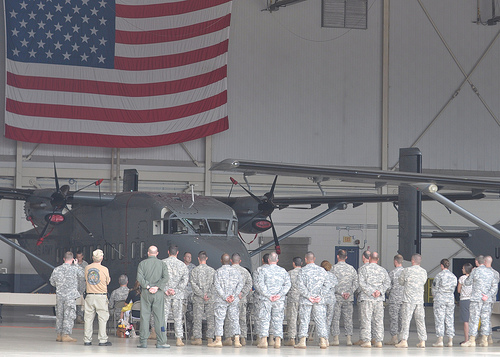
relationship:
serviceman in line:
[354, 247, 392, 343] [49, 244, 497, 345]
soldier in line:
[395, 254, 428, 348] [162, 248, 490, 354]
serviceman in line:
[431, 260, 457, 346] [49, 244, 497, 345]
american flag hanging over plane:
[6, 3, 263, 142] [0, 167, 484, 291]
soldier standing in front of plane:
[205, 241, 310, 346] [0, 167, 484, 291]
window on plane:
[164, 219, 236, 234] [19, 176, 486, 313]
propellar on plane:
[16, 166, 124, 261] [0, 167, 484, 291]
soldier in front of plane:
[398, 253, 428, 345] [4, 162, 498, 319]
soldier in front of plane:
[189, 244, 219, 347] [9, 164, 499, 299]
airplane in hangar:
[0, 165, 483, 289] [5, 10, 483, 314]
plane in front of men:
[42, 144, 410, 298] [109, 243, 407, 321]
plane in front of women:
[42, 144, 410, 298] [81, 234, 408, 355]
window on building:
[320, 4, 368, 26] [2, 2, 499, 309]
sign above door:
[343, 234, 353, 244] [334, 244, 356, 266]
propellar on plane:
[0, 154, 104, 246] [0, 167, 484, 291]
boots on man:
[202, 337, 244, 347] [207, 251, 245, 347]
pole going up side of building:
[379, 1, 391, 278] [2, 2, 499, 309]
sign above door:
[343, 236, 352, 242] [328, 236, 363, 311]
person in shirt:
[71, 240, 128, 355] [82, 262, 110, 292]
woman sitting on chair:
[117, 279, 142, 327] [127, 298, 140, 321]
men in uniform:
[137, 244, 172, 348] [137, 257, 167, 341]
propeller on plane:
[229, 172, 308, 247] [2, 165, 426, 270]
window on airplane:
[164, 219, 236, 234] [0, 165, 483, 289]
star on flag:
[94, 54, 108, 64] [2, 2, 230, 143]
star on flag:
[98, 37, 110, 46] [2, 2, 230, 143]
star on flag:
[61, 51, 73, 62] [2, 2, 230, 143]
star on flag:
[98, 12, 108, 28] [2, 2, 230, 143]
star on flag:
[25, 26, 37, 40] [2, 2, 230, 143]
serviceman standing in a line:
[39, 245, 89, 336] [98, 225, 454, 357]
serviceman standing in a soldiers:
[39, 245, 89, 336] [384, 254, 407, 346]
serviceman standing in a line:
[158, 241, 190, 348] [40, 301, 374, 357]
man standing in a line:
[207, 253, 244, 347] [83, 250, 229, 357]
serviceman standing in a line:
[52, 238, 372, 337] [58, 235, 498, 352]